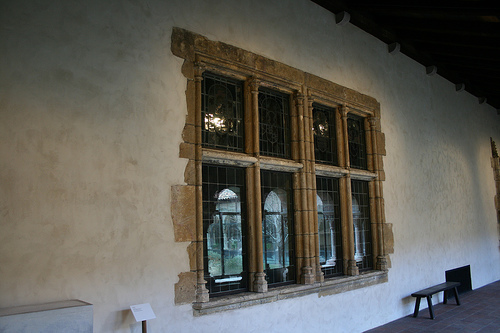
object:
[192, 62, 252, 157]
windows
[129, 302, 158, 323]
plaque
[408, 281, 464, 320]
chair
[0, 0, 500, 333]
wall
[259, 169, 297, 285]
reflection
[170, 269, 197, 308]
rock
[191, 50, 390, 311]
trim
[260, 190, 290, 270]
tree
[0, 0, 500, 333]
building